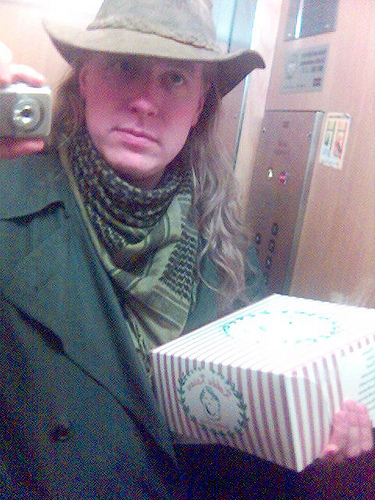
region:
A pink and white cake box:
[144, 269, 373, 473]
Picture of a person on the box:
[187, 385, 225, 425]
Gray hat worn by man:
[47, 2, 265, 85]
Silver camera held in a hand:
[2, 81, 56, 154]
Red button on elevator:
[272, 168, 297, 189]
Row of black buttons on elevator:
[260, 217, 278, 287]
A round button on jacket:
[48, 419, 75, 443]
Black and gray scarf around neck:
[74, 147, 212, 369]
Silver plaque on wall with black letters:
[278, 43, 331, 99]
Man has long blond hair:
[54, 60, 255, 308]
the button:
[34, 411, 73, 451]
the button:
[42, 412, 76, 438]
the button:
[42, 403, 114, 494]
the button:
[45, 416, 105, 462]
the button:
[20, 397, 106, 457]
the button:
[6, 397, 133, 485]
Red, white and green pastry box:
[164, 303, 371, 456]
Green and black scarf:
[54, 158, 220, 334]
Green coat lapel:
[5, 242, 172, 472]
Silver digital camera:
[0, 85, 57, 134]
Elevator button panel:
[249, 107, 333, 289]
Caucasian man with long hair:
[59, 4, 255, 300]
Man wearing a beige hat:
[50, 0, 243, 188]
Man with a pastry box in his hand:
[69, 38, 370, 468]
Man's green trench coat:
[4, 160, 272, 491]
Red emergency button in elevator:
[252, 159, 295, 195]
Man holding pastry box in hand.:
[130, 290, 370, 476]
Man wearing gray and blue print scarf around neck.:
[45, 113, 234, 353]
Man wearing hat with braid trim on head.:
[35, 0, 275, 88]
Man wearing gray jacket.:
[8, 150, 264, 495]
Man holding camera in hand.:
[4, 55, 66, 164]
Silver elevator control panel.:
[242, 104, 321, 319]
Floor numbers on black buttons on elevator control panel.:
[248, 210, 281, 289]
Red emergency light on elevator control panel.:
[277, 167, 295, 194]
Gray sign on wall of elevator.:
[278, 44, 338, 97]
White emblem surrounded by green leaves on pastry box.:
[172, 364, 265, 442]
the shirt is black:
[36, 375, 104, 452]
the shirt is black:
[43, 417, 95, 462]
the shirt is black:
[34, 407, 145, 488]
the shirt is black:
[94, 423, 169, 487]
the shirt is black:
[67, 392, 115, 448]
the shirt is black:
[99, 439, 136, 478]